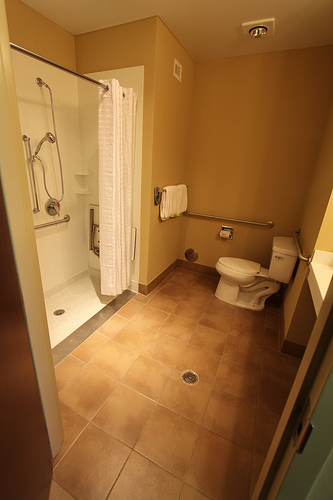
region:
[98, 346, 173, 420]
Brown tiled floor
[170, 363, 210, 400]
Drain on a tiled floor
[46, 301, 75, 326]
Drain on a white shower floor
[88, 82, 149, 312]
White shower curtain hanging up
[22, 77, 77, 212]
Silver shower faucet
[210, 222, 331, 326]
White toilet next to a wall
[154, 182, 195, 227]
Two white bath towels hanging up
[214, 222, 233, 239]
White roll of toilet paper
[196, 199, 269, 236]
Silver handle on a wall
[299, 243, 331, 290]
White counter top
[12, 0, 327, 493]
photograph of clean bathroom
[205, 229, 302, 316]
white toilet with closed lid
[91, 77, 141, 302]
white shower curtain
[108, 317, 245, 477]
light brown ceramic tile floor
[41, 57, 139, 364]
shower with no bath tub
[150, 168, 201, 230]
white towels hanging on wall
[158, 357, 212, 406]
silver drain in middle of tile floor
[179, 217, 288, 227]
silver safety handrails along wall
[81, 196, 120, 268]
pull out chair on shower wall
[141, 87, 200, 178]
mustard colored walls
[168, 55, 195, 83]
Air vent at top of wall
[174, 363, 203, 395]
Floor drain in tile floor.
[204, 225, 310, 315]
Toilet with silver grab bar above it.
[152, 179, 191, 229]
White towels hanging on a towel rack on wall.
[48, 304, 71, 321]
Drain in shower floor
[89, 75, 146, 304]
White waffle patterned shower curtain.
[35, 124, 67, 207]
Hand held shower nozzle.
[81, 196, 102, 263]
Fold down shower seat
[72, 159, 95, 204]
Two small shelves in corner of shower.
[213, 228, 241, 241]
toilet paper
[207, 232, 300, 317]
white porcelain toilet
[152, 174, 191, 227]
white towel hanging on a bar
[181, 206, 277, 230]
grey metal assistance bar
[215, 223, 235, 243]
toilet paper dispenser with a white roll of paper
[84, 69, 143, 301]
textured white shower curtain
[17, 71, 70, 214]
metal shower nozzle with removable handle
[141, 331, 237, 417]
brown tile floor with drain grate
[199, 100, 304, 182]
blank brown wall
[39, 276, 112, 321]
white shower floor with drain grate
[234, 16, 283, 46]
light fixture with metal center and black edging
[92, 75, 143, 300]
A WHITE SHOWER CURTAIN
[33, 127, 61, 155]
A METAL SHOWER HEAD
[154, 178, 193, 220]
TWO WHITE HAND TOWELS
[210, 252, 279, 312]
A WHITE TOILET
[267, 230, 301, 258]
A WHITE TOILET TANK COVER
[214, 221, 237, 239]
A ROLL OF TOILET PAPER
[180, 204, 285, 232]
A BATHROOM WALL RAIL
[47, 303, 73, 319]
A SHOWER DRAIN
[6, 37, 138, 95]
A METAL SHOWER CURTAIN ROD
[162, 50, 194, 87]
A BATHROOM VENT